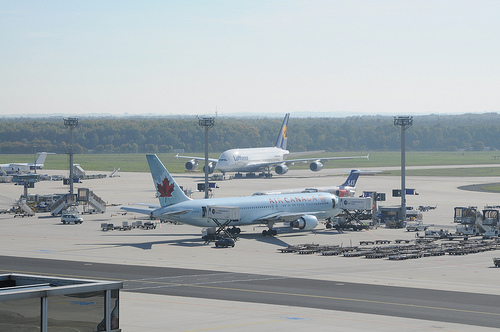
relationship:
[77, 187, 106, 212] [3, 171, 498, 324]
stairs on tarmac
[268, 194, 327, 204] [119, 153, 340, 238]
logo on plane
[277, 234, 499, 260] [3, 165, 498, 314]
equipment on runway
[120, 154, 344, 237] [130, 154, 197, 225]
airplane with tail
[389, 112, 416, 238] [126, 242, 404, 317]
lights on runaway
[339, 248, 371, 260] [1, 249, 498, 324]
rack on runway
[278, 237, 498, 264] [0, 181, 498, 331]
pallets on tarmac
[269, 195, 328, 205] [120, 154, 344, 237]
name on airplane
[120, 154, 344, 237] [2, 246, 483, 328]
airplane parked on tarmac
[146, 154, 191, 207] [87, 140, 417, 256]
tail mounted on plane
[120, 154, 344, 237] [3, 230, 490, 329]
airplane parked on tarmac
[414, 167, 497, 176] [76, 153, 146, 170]
grass growing in field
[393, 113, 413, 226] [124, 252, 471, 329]
pole mounted on tarmac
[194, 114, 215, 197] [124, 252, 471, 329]
pole mounted on tarmac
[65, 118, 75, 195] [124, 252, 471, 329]
pole mounted on tarmac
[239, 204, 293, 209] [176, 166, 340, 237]
windows mounted on airplane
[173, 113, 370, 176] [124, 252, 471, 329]
airplane parked on tarmac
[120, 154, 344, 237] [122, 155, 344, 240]
airplane parked on tarmac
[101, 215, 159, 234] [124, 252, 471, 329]
carts parked on tarmac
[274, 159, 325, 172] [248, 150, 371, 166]
engines mounted on wing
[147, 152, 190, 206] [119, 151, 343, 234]
tail mounted on airplane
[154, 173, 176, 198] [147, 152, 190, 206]
maple leaf painted on tail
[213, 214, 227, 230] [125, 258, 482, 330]
ramp on top of tarmac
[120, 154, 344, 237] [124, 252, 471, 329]
airplane parked on tarmac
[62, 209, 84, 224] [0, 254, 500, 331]
van parked on tarmac